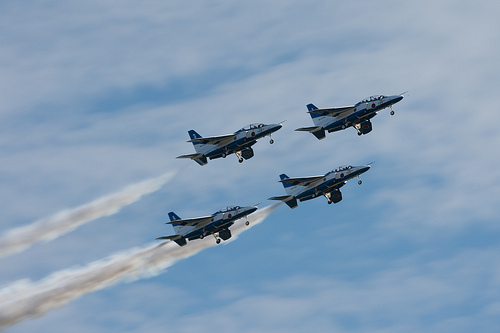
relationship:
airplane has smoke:
[185, 117, 280, 163] [1, 160, 176, 261]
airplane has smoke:
[274, 164, 367, 209] [0, 242, 171, 333]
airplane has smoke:
[163, 205, 254, 249] [0, 242, 171, 333]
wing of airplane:
[187, 132, 234, 147] [185, 117, 280, 163]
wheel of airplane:
[232, 146, 248, 165] [185, 117, 280, 163]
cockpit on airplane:
[238, 121, 265, 133] [185, 117, 280, 163]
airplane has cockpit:
[185, 117, 280, 163] [238, 120, 264, 136]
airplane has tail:
[185, 117, 280, 163] [188, 129, 208, 152]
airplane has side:
[185, 117, 280, 163] [194, 138, 242, 158]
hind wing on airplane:
[176, 150, 198, 161] [185, 117, 280, 163]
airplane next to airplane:
[185, 117, 280, 163] [274, 164, 367, 209]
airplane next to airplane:
[163, 205, 254, 249] [300, 91, 403, 143]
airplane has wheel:
[185, 117, 280, 163] [232, 146, 248, 165]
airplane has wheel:
[185, 117, 280, 163] [268, 133, 276, 146]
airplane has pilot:
[163, 205, 254, 249] [226, 204, 237, 215]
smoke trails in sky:
[1, 160, 176, 261] [5, 4, 488, 332]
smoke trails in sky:
[0, 242, 171, 333] [5, 4, 488, 332]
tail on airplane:
[188, 129, 208, 152] [185, 117, 280, 163]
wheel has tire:
[268, 133, 276, 146] [268, 138, 275, 146]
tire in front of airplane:
[268, 138, 275, 146] [185, 117, 280, 163]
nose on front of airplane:
[266, 123, 283, 136] [185, 117, 280, 163]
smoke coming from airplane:
[1, 160, 176, 261] [185, 117, 280, 163]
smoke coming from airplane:
[0, 242, 171, 333] [274, 164, 367, 209]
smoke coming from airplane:
[0, 242, 171, 333] [163, 205, 254, 249]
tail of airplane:
[188, 129, 208, 152] [185, 117, 280, 163]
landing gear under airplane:
[240, 146, 257, 161] [185, 117, 280, 163]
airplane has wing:
[185, 117, 280, 163] [187, 132, 234, 147]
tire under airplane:
[268, 138, 275, 146] [185, 117, 280, 163]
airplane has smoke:
[163, 205, 254, 249] [1, 160, 176, 261]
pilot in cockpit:
[252, 122, 259, 127] [238, 120, 264, 136]